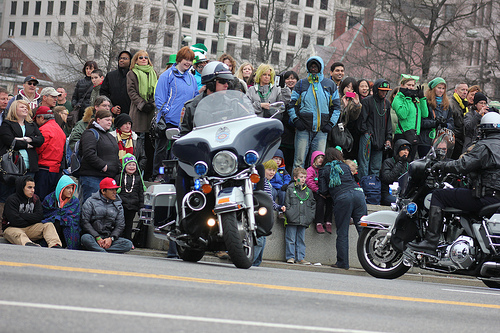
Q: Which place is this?
A: It is a road.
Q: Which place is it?
A: It is a road.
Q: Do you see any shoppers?
A: No, there are no shoppers.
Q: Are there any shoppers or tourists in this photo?
A: No, there are no shoppers or tourists.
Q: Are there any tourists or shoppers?
A: No, there are no shoppers or tourists.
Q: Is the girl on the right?
A: Yes, the girl is on the right of the image.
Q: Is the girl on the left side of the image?
A: No, the girl is on the right of the image.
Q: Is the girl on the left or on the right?
A: The girl is on the right of the image.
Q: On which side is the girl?
A: The girl is on the right of the image.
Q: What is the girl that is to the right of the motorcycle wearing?
A: The girl is wearing a coat.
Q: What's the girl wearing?
A: The girl is wearing a coat.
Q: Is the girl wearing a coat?
A: Yes, the girl is wearing a coat.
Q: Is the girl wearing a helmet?
A: No, the girl is wearing a coat.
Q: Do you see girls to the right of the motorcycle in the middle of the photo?
A: Yes, there is a girl to the right of the motorbike.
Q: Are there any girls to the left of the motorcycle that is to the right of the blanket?
A: No, the girl is to the right of the motorbike.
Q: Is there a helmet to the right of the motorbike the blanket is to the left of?
A: No, there is a girl to the right of the motorbike.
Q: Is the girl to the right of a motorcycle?
A: Yes, the girl is to the right of a motorcycle.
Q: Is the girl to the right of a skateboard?
A: No, the girl is to the right of a motorcycle.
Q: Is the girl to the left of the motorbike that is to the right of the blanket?
A: No, the girl is to the right of the motorbike.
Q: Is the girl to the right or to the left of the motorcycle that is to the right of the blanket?
A: The girl is to the right of the motorcycle.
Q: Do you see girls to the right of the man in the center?
A: Yes, there is a girl to the right of the man.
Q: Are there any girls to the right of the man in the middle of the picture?
A: Yes, there is a girl to the right of the man.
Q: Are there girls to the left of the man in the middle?
A: No, the girl is to the right of the man.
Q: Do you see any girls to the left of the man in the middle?
A: No, the girl is to the right of the man.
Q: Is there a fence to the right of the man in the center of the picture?
A: No, there is a girl to the right of the man.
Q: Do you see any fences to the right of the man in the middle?
A: No, there is a girl to the right of the man.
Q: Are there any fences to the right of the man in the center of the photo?
A: No, there is a girl to the right of the man.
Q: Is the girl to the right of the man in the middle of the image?
A: Yes, the girl is to the right of the man.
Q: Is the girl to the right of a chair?
A: No, the girl is to the right of the man.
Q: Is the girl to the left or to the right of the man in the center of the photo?
A: The girl is to the right of the man.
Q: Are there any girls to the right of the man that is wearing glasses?
A: Yes, there is a girl to the right of the man.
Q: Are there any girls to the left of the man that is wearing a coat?
A: No, the girl is to the right of the man.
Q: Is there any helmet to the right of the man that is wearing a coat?
A: No, there is a girl to the right of the man.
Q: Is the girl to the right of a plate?
A: No, the girl is to the right of a man.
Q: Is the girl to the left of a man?
A: No, the girl is to the right of a man.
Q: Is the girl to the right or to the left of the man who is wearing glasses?
A: The girl is to the right of the man.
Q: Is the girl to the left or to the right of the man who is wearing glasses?
A: The girl is to the right of the man.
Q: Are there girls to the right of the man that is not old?
A: Yes, there is a girl to the right of the man.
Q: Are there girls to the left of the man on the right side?
A: No, the girl is to the right of the man.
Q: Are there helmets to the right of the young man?
A: No, there is a girl to the right of the man.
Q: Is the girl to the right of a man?
A: Yes, the girl is to the right of a man.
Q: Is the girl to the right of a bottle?
A: No, the girl is to the right of a man.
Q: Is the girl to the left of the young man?
A: No, the girl is to the right of the man.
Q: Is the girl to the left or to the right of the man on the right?
A: The girl is to the right of the man.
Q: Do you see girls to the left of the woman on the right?
A: Yes, there is a girl to the left of the woman.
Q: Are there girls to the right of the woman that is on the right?
A: No, the girl is to the left of the woman.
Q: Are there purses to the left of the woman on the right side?
A: No, there is a girl to the left of the woman.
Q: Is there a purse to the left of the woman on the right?
A: No, there is a girl to the left of the woman.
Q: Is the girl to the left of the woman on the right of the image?
A: Yes, the girl is to the left of the woman.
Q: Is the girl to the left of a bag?
A: No, the girl is to the left of the woman.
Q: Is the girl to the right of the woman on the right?
A: No, the girl is to the left of the woman.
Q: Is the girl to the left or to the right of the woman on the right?
A: The girl is to the left of the woman.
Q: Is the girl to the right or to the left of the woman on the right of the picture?
A: The girl is to the left of the woman.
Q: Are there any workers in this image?
A: No, there are no workers.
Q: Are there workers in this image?
A: No, there are no workers.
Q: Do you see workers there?
A: No, there are no workers.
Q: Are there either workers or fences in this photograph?
A: No, there are no workers or fences.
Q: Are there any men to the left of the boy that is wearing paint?
A: Yes, there is a man to the left of the boy.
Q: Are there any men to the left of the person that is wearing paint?
A: Yes, there is a man to the left of the boy.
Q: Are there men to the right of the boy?
A: No, the man is to the left of the boy.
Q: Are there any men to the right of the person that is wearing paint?
A: No, the man is to the left of the boy.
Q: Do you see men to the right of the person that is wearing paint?
A: No, the man is to the left of the boy.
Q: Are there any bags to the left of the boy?
A: No, there is a man to the left of the boy.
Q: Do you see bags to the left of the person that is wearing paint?
A: No, there is a man to the left of the boy.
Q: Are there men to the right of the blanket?
A: Yes, there is a man to the right of the blanket.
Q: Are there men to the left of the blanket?
A: No, the man is to the right of the blanket.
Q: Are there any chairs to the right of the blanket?
A: No, there is a man to the right of the blanket.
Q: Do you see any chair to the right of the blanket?
A: No, there is a man to the right of the blanket.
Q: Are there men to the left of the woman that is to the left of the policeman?
A: Yes, there is a man to the left of the woman.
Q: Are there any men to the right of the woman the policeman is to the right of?
A: No, the man is to the left of the woman.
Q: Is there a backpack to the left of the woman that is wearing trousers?
A: No, there is a man to the left of the woman.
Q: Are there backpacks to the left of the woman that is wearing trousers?
A: No, there is a man to the left of the woman.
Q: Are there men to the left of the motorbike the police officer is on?
A: Yes, there is a man to the left of the motorcycle.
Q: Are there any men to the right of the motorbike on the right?
A: No, the man is to the left of the motorbike.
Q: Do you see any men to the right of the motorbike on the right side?
A: No, the man is to the left of the motorbike.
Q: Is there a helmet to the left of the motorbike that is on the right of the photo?
A: No, there is a man to the left of the motorbike.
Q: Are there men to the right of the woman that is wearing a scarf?
A: Yes, there is a man to the right of the woman.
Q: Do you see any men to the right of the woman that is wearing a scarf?
A: Yes, there is a man to the right of the woman.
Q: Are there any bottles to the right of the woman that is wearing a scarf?
A: No, there is a man to the right of the woman.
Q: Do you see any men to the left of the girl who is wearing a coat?
A: Yes, there is a man to the left of the girl.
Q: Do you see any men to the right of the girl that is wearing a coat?
A: No, the man is to the left of the girl.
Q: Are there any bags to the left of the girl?
A: No, there is a man to the left of the girl.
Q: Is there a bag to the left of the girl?
A: No, there is a man to the left of the girl.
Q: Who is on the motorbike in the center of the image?
A: The man is on the motorcycle.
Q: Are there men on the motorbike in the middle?
A: Yes, there is a man on the motorbike.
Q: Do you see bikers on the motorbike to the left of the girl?
A: No, there is a man on the motorbike.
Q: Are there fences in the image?
A: No, there are no fences.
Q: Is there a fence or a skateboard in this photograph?
A: No, there are no fences or skateboards.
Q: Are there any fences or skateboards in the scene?
A: No, there are no fences or skateboards.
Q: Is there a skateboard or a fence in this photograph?
A: No, there are no fences or skateboards.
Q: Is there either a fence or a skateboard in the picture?
A: No, there are no fences or skateboards.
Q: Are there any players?
A: No, there are no players.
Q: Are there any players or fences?
A: No, there are no players or fences.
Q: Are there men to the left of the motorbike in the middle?
A: Yes, there is a man to the left of the motorcycle.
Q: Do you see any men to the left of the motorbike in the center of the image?
A: Yes, there is a man to the left of the motorcycle.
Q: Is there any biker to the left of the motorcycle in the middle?
A: No, there is a man to the left of the motorbike.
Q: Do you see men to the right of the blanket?
A: Yes, there is a man to the right of the blanket.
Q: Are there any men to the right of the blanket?
A: Yes, there is a man to the right of the blanket.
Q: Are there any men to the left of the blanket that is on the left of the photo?
A: No, the man is to the right of the blanket.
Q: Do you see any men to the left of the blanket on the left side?
A: No, the man is to the right of the blanket.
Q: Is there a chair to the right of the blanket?
A: No, there is a man to the right of the blanket.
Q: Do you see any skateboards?
A: No, there are no skateboards.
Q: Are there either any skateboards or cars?
A: No, there are no skateboards or cars.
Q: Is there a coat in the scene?
A: Yes, there is a coat.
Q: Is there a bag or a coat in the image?
A: Yes, there is a coat.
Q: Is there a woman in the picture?
A: Yes, there is a woman.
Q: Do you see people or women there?
A: Yes, there is a woman.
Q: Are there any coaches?
A: No, there are no coaches.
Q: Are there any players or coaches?
A: No, there are no coaches or players.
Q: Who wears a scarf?
A: The woman wears a scarf.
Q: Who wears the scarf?
A: The woman wears a scarf.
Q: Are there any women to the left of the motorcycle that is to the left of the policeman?
A: Yes, there is a woman to the left of the motorbike.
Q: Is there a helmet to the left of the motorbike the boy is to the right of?
A: No, there is a woman to the left of the motorbike.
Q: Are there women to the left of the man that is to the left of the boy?
A: Yes, there is a woman to the left of the man.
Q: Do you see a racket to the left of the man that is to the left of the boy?
A: No, there is a woman to the left of the man.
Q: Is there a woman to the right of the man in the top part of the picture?
A: Yes, there is a woman to the right of the man.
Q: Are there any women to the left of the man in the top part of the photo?
A: No, the woman is to the right of the man.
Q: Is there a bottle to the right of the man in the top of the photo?
A: No, there is a woman to the right of the man.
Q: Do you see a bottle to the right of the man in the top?
A: No, there is a woman to the right of the man.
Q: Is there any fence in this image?
A: No, there are no fences.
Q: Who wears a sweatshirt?
A: The man wears a sweatshirt.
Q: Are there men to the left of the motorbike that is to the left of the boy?
A: Yes, there is a man to the left of the motorbike.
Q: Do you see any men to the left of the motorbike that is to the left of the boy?
A: Yes, there is a man to the left of the motorbike.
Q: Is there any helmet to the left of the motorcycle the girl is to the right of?
A: No, there is a man to the left of the motorcycle.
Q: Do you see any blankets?
A: Yes, there is a blanket.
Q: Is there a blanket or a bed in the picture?
A: Yes, there is a blanket.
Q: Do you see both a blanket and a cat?
A: No, there is a blanket but no cats.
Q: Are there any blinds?
A: No, there are no blinds.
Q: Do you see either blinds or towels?
A: No, there are no blinds or towels.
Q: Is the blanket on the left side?
A: Yes, the blanket is on the left of the image.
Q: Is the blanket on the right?
A: No, the blanket is on the left of the image.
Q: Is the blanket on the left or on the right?
A: The blanket is on the left of the image.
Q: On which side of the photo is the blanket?
A: The blanket is on the left of the image.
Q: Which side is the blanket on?
A: The blanket is on the left of the image.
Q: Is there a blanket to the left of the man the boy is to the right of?
A: Yes, there is a blanket to the left of the man.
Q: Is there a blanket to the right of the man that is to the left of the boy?
A: No, the blanket is to the left of the man.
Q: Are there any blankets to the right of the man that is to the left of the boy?
A: No, the blanket is to the left of the man.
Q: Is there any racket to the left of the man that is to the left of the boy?
A: No, there is a blanket to the left of the man.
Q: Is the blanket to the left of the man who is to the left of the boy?
A: Yes, the blanket is to the left of the man.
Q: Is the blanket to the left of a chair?
A: No, the blanket is to the left of the man.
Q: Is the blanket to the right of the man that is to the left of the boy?
A: No, the blanket is to the left of the man.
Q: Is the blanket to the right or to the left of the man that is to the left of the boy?
A: The blanket is to the left of the man.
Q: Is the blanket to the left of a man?
A: Yes, the blanket is to the left of a man.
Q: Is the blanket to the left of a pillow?
A: No, the blanket is to the left of a man.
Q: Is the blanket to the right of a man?
A: No, the blanket is to the left of a man.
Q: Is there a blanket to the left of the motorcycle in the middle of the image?
A: Yes, there is a blanket to the left of the motorcycle.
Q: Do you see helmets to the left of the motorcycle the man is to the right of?
A: No, there is a blanket to the left of the motorcycle.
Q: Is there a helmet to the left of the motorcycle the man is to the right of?
A: No, there is a blanket to the left of the motorcycle.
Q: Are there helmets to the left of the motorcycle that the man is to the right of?
A: No, there is a blanket to the left of the motorcycle.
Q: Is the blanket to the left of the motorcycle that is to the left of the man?
A: Yes, the blanket is to the left of the motorcycle.